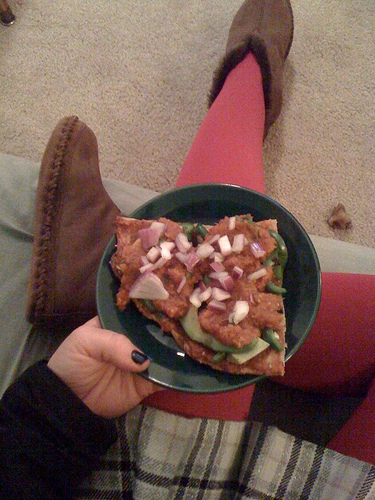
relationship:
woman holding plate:
[0, 0, 375, 495] [65, 171, 350, 402]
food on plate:
[100, 197, 291, 386] [65, 171, 350, 402]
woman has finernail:
[0, 0, 375, 495] [129, 345, 151, 370]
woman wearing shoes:
[0, 0, 375, 495] [26, 3, 302, 332]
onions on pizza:
[133, 228, 241, 272] [105, 196, 293, 378]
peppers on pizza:
[176, 227, 278, 362] [105, 196, 293, 378]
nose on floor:
[308, 189, 359, 242] [4, 3, 373, 237]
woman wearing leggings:
[0, 0, 375, 495] [162, 44, 372, 474]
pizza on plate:
[100, 208, 295, 393] [69, 166, 326, 399]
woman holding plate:
[0, 0, 375, 495] [90, 172, 331, 400]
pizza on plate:
[100, 208, 295, 393] [90, 172, 331, 400]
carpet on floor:
[4, 3, 372, 242] [4, 3, 373, 237]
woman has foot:
[5, 5, 359, 496] [13, 107, 127, 329]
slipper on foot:
[20, 112, 133, 343] [13, 107, 127, 329]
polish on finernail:
[119, 343, 155, 368] [124, 342, 151, 373]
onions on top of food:
[193, 239, 236, 256] [73, 189, 309, 392]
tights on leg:
[136, 80, 370, 412] [92, 223, 373, 367]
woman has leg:
[0, 0, 375, 495] [92, 223, 373, 367]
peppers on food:
[264, 226, 293, 302] [100, 197, 291, 386]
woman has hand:
[0, 0, 375, 495] [26, 280, 175, 427]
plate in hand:
[90, 172, 331, 400] [26, 280, 175, 427]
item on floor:
[316, 194, 365, 249] [4, 3, 373, 237]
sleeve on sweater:
[0, 340, 138, 495] [6, 328, 121, 497]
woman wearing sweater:
[0, 0, 375, 495] [6, 328, 121, 497]